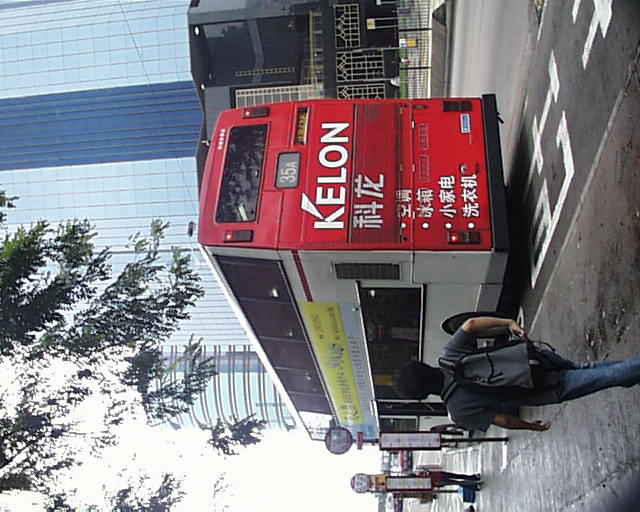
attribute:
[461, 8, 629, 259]
road — grey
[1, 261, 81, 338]
leaves — green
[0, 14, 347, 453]
buildings — blue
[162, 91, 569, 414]
bus — white, red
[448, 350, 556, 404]
bagpack — black, grey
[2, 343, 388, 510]
sky — white